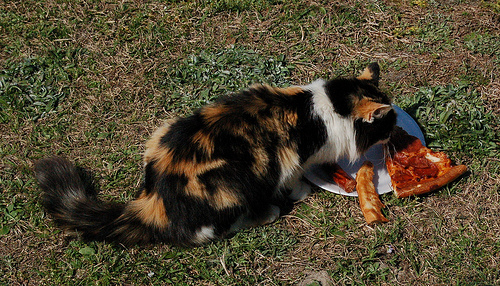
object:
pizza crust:
[354, 158, 387, 227]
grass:
[1, 0, 498, 284]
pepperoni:
[390, 170, 414, 186]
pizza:
[384, 126, 467, 197]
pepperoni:
[409, 154, 439, 180]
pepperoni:
[395, 131, 422, 155]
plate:
[302, 106, 427, 198]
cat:
[33, 62, 396, 246]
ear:
[363, 100, 393, 124]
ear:
[356, 61, 381, 85]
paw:
[284, 176, 311, 204]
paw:
[243, 201, 280, 227]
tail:
[29, 153, 166, 243]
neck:
[304, 77, 357, 171]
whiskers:
[373, 137, 399, 169]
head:
[321, 60, 399, 144]